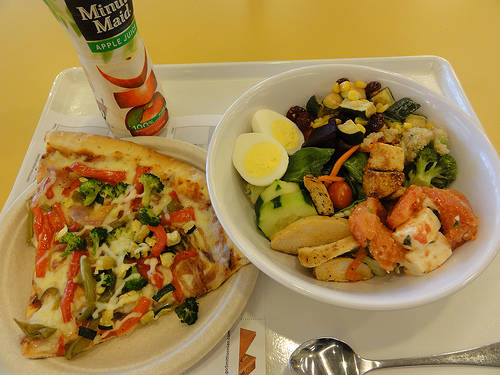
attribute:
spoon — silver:
[288, 337, 499, 370]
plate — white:
[3, 140, 246, 373]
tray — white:
[7, 69, 498, 364]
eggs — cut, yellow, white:
[222, 120, 296, 180]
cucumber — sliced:
[256, 187, 304, 227]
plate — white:
[207, 63, 497, 315]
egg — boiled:
[253, 108, 300, 153]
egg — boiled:
[237, 136, 287, 183]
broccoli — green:
[90, 229, 106, 254]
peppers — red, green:
[145, 226, 173, 262]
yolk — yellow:
[248, 143, 278, 176]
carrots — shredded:
[326, 148, 354, 183]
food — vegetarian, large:
[16, 121, 253, 359]